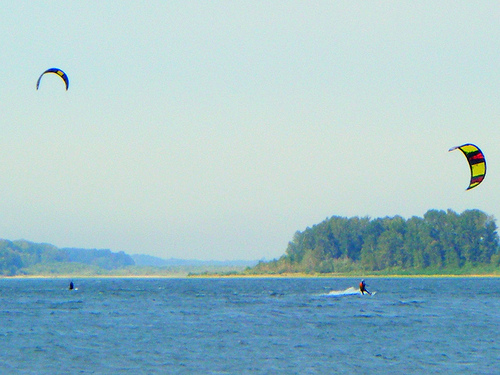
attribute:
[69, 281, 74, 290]
boarder — standing, kitesurfing, hanging on, kite surfing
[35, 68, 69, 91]
kite — blue, yellow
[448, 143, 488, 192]
kite — black, red, yellow, blue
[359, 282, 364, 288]
vest — red, orange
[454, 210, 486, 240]
tree — green, tall, leafy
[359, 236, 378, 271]
tree — tall, green, leafy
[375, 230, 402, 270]
tree — tall, green, leafy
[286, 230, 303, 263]
tree — tall, green, leafy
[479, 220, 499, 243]
tree — green, tall, leafy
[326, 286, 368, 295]
wake — white, small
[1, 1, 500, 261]
sky — cloud free, hazy, gray, cloudy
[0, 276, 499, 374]
lake — water, blue, large, choppy, waveless, dark, calm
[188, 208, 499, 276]
vegetation — green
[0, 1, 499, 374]
outside — summer, hot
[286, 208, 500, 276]
patch — green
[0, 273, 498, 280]
shoreline — beach